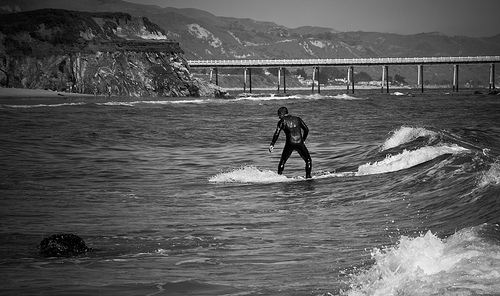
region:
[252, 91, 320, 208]
Man in the water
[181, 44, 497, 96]
Tall bridge over the water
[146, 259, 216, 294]
Small ripples in the water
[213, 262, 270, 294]
Small ripples in the water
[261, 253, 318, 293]
Small ripples in the water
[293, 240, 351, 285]
Small ripples in the water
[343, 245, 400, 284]
Small ripples in the water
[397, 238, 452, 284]
Small ripples in the water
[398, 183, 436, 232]
Small ripples in the water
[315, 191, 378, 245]
Small ripples in the water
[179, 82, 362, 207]
the man is surfing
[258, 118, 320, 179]
the man is wearing a wet suit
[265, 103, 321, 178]
a surfer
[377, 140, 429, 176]
the water is white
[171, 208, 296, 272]
the oceans water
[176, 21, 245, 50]
the mountain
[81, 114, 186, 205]
the water is clear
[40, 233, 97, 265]
an object in the water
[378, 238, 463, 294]
the water is white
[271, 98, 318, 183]
the surfer is standing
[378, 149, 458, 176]
a small wave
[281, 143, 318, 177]
the surfers leg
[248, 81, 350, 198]
this is a person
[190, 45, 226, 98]
a pillar in a bridge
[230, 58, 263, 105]
a pillar in a bridge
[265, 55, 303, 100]
a pillar in a bridge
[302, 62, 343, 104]
a pillar in a bridge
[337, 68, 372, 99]
a pillar in a bridge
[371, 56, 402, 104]
a pillar in a bridge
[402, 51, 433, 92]
a pillar in a bridge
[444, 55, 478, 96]
a pillar in a bridge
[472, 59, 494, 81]
a pillar in a bridge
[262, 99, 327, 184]
person in wet suit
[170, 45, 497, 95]
a long bridge across the pier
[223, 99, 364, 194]
person riding a wave with surf board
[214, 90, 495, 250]
the ocean tidal wave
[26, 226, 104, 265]
a small rock protruding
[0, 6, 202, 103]
rocky fields and a beach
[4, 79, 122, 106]
a beach shore line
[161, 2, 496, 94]
mountain ranges and rocky roads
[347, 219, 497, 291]
tidal wave of ocean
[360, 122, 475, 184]
the waves of an ocean